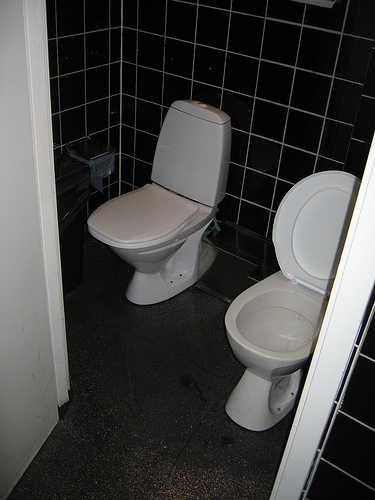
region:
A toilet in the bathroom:
[224, 169, 361, 430]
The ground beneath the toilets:
[5, 267, 299, 499]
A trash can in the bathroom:
[55, 152, 86, 293]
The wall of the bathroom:
[46, 3, 373, 239]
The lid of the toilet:
[87, 183, 197, 244]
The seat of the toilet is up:
[272, 170, 361, 294]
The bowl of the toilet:
[235, 289, 317, 353]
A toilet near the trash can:
[86, 101, 230, 305]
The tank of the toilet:
[172, 100, 228, 123]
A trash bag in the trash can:
[56, 155, 89, 230]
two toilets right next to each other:
[76, 75, 365, 437]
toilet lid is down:
[87, 181, 185, 253]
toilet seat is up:
[257, 163, 359, 316]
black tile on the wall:
[290, 302, 374, 499]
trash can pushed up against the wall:
[49, 147, 96, 295]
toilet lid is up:
[269, 163, 361, 300]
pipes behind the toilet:
[206, 218, 223, 242]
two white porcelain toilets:
[75, 82, 363, 437]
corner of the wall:
[254, 145, 374, 498]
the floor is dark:
[0, 235, 300, 498]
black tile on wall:
[236, 199, 269, 234]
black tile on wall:
[215, 191, 240, 223]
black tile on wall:
[268, 177, 293, 213]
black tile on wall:
[240, 166, 272, 207]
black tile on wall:
[225, 160, 243, 199]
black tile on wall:
[312, 153, 341, 179]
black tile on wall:
[279, 144, 316, 187]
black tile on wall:
[245, 133, 279, 176]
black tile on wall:
[229, 127, 248, 169]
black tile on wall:
[254, 59, 290, 108]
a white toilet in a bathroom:
[82, 97, 252, 311]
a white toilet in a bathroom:
[225, 167, 368, 432]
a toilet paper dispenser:
[60, 133, 118, 188]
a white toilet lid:
[81, 181, 203, 244]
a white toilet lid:
[270, 171, 365, 301]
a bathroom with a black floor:
[0, 204, 301, 498]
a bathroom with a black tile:
[11, 2, 372, 315]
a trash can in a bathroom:
[32, 143, 89, 299]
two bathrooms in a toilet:
[83, 99, 362, 442]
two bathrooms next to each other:
[80, 101, 358, 434]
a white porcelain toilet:
[86, 98, 232, 306]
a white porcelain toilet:
[222, 269, 324, 430]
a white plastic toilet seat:
[272, 171, 358, 295]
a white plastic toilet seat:
[86, 184, 198, 245]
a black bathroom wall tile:
[236, 197, 270, 238]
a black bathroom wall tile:
[240, 167, 274, 208]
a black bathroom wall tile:
[245, 133, 282, 177]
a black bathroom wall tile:
[248, 96, 286, 141]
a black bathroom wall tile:
[255, 58, 295, 106]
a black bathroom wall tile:
[259, 17, 301, 67]